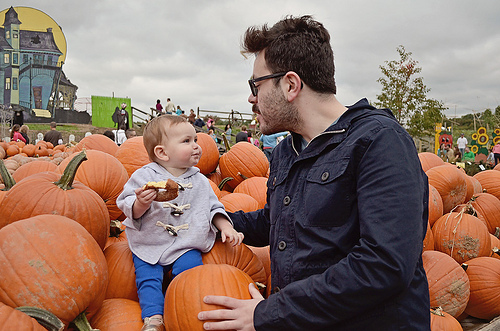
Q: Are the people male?
A: No, they are both male and female.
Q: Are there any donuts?
A: Yes, there is a donut.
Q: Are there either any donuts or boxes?
A: Yes, there is a donut.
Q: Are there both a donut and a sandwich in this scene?
A: No, there is a donut but no sandwiches.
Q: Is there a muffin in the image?
A: No, there are no muffins.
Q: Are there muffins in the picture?
A: No, there are no muffins.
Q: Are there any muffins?
A: No, there are no muffins.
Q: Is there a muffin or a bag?
A: No, there are no muffins or bags.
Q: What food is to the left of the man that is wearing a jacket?
A: The food is a donut.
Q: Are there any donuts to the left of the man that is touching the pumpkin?
A: Yes, there is a donut to the left of the man.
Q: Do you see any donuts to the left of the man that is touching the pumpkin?
A: Yes, there is a donut to the left of the man.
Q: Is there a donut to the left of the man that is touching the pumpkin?
A: Yes, there is a donut to the left of the man.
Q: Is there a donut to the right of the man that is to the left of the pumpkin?
A: No, the donut is to the left of the man.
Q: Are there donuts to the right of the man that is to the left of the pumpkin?
A: No, the donut is to the left of the man.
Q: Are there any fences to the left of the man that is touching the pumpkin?
A: No, there is a donut to the left of the man.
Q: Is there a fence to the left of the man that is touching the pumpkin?
A: No, there is a donut to the left of the man.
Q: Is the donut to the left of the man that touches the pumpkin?
A: Yes, the donut is to the left of the man.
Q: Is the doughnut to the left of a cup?
A: No, the doughnut is to the left of the man.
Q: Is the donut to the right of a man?
A: No, the donut is to the left of a man.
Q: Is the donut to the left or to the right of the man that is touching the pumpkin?
A: The donut is to the left of the man.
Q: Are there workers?
A: No, there are no workers.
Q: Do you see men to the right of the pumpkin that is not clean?
A: Yes, there is a man to the right of the pumpkin.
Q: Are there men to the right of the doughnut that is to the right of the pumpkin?
A: Yes, there is a man to the right of the doughnut.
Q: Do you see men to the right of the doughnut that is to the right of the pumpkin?
A: Yes, there is a man to the right of the doughnut.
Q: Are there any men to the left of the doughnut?
A: No, the man is to the right of the doughnut.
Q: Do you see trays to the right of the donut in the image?
A: No, there is a man to the right of the donut.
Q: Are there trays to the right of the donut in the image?
A: No, there is a man to the right of the donut.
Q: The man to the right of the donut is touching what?
A: The man is touching the pumpkin.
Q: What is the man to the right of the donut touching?
A: The man is touching the pumpkin.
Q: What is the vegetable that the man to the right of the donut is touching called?
A: The vegetable is a pumpkin.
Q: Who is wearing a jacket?
A: The man is wearing a jacket.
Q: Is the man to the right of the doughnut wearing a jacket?
A: Yes, the man is wearing a jacket.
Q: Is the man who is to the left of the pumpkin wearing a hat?
A: No, the man is wearing a jacket.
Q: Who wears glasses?
A: The man wears glasses.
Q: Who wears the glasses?
A: The man wears glasses.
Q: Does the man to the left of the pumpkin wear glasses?
A: Yes, the man wears glasses.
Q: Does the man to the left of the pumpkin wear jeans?
A: No, the man wears glasses.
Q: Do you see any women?
A: Yes, there is a woman.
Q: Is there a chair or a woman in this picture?
A: Yes, there is a woman.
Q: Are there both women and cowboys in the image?
A: No, there is a woman but no cowboys.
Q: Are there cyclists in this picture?
A: No, there are no cyclists.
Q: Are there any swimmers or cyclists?
A: No, there are no cyclists or swimmers.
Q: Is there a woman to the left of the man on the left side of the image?
A: Yes, there is a woman to the left of the man.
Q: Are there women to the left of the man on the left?
A: Yes, there is a woman to the left of the man.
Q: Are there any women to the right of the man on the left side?
A: No, the woman is to the left of the man.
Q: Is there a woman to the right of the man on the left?
A: No, the woman is to the left of the man.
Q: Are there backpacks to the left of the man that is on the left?
A: No, there is a woman to the left of the man.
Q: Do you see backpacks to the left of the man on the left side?
A: No, there is a woman to the left of the man.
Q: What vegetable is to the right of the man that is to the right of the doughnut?
A: The vegetable is a pumpkin.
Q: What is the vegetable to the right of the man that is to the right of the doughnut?
A: The vegetable is a pumpkin.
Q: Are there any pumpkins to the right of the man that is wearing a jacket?
A: Yes, there is a pumpkin to the right of the man.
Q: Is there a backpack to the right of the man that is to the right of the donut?
A: No, there is a pumpkin to the right of the man.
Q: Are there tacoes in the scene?
A: No, there are no tacoes.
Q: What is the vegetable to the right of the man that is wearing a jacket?
A: The vegetable is a pumpkin.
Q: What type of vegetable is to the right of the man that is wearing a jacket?
A: The vegetable is a pumpkin.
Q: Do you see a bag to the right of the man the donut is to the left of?
A: No, there is a pumpkin to the right of the man.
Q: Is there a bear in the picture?
A: No, there are no bears.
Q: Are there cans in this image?
A: No, there are no cans.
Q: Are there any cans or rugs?
A: No, there are no cans or rugs.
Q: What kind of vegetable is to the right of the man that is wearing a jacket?
A: The vegetable is a pumpkin.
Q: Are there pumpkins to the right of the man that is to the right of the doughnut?
A: Yes, there is a pumpkin to the right of the man.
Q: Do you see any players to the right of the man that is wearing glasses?
A: No, there is a pumpkin to the right of the man.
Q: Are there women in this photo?
A: Yes, there is a woman.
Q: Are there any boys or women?
A: Yes, there is a woman.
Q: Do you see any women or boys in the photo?
A: Yes, there is a woman.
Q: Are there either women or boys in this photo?
A: Yes, there is a woman.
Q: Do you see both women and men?
A: Yes, there are both a woman and a man.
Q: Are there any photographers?
A: No, there are no photographers.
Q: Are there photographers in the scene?
A: No, there are no photographers.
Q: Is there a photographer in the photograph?
A: No, there are no photographers.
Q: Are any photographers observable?
A: No, there are no photographers.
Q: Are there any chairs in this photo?
A: No, there are no chairs.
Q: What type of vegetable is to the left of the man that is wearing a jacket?
A: The vegetable is a pumpkin.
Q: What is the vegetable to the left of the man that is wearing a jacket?
A: The vegetable is a pumpkin.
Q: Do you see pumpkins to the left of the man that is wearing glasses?
A: Yes, there is a pumpkin to the left of the man.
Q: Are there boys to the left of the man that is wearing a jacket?
A: No, there is a pumpkin to the left of the man.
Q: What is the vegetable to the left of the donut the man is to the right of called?
A: The vegetable is a pumpkin.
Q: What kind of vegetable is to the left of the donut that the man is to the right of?
A: The vegetable is a pumpkin.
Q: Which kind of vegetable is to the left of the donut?
A: The vegetable is a pumpkin.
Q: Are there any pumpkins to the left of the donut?
A: Yes, there is a pumpkin to the left of the donut.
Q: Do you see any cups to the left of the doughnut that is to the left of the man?
A: No, there is a pumpkin to the left of the doughnut.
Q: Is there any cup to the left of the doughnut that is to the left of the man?
A: No, there is a pumpkin to the left of the doughnut.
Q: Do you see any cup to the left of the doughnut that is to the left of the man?
A: No, there is a pumpkin to the left of the doughnut.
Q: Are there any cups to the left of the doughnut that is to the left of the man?
A: No, there is a pumpkin to the left of the doughnut.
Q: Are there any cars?
A: No, there are no cars.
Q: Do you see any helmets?
A: No, there are no helmets.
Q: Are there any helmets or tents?
A: No, there are no helmets or tents.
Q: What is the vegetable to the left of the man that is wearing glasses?
A: The vegetable is a pumpkin.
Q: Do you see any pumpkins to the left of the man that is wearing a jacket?
A: Yes, there is a pumpkin to the left of the man.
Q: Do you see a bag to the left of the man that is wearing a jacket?
A: No, there is a pumpkin to the left of the man.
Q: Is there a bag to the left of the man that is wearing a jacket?
A: No, there is a pumpkin to the left of the man.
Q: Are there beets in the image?
A: No, there are no beets.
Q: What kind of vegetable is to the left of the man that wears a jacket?
A: The vegetable is a pumpkin.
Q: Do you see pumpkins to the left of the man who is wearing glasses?
A: Yes, there is a pumpkin to the left of the man.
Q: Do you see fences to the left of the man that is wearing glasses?
A: No, there is a pumpkin to the left of the man.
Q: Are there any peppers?
A: No, there are no peppers.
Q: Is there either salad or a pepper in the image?
A: No, there are no peppers or salad.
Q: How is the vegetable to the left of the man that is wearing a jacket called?
A: The vegetable is a pumpkin.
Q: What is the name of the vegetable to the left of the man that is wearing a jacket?
A: The vegetable is a pumpkin.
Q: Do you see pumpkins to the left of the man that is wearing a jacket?
A: Yes, there is a pumpkin to the left of the man.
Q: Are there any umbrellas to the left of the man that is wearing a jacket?
A: No, there is a pumpkin to the left of the man.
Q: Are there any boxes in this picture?
A: No, there are no boxes.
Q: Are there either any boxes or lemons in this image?
A: No, there are no boxes or lemons.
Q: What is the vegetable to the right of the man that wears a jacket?
A: The vegetable is a pumpkin.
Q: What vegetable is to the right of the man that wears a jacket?
A: The vegetable is a pumpkin.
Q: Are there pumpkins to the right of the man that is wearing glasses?
A: Yes, there is a pumpkin to the right of the man.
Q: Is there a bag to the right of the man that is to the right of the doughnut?
A: No, there is a pumpkin to the right of the man.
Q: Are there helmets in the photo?
A: No, there are no helmets.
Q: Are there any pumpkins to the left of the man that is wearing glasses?
A: Yes, there is a pumpkin to the left of the man.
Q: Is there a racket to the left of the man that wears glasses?
A: No, there is a pumpkin to the left of the man.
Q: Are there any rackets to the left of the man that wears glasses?
A: No, there is a pumpkin to the left of the man.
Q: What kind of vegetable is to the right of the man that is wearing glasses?
A: The vegetable is a pumpkin.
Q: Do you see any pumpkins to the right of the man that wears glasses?
A: Yes, there is a pumpkin to the right of the man.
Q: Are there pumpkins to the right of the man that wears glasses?
A: Yes, there is a pumpkin to the right of the man.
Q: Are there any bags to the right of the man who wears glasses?
A: No, there is a pumpkin to the right of the man.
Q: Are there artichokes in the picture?
A: No, there are no artichokes.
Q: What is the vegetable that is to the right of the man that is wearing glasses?
A: The vegetable is a pumpkin.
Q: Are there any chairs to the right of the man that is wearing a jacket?
A: No, there is a pumpkin to the right of the man.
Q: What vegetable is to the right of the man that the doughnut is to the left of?
A: The vegetable is a pumpkin.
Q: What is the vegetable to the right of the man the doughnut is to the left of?
A: The vegetable is a pumpkin.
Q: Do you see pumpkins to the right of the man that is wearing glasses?
A: Yes, there is a pumpkin to the right of the man.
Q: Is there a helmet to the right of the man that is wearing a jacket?
A: No, there is a pumpkin to the right of the man.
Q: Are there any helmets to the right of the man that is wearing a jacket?
A: No, there is a pumpkin to the right of the man.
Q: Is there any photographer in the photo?
A: No, there are no photographers.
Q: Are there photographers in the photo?
A: No, there are no photographers.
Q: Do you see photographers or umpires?
A: No, there are no photographers or umpires.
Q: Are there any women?
A: Yes, there is a woman.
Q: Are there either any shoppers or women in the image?
A: Yes, there is a woman.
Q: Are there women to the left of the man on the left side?
A: Yes, there is a woman to the left of the man.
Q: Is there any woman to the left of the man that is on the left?
A: Yes, there is a woman to the left of the man.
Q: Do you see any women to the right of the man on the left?
A: No, the woman is to the left of the man.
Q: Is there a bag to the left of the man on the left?
A: No, there is a woman to the left of the man.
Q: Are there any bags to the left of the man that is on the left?
A: No, there is a woman to the left of the man.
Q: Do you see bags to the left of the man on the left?
A: No, there is a woman to the left of the man.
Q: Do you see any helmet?
A: No, there are no helmets.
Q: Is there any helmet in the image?
A: No, there are no helmets.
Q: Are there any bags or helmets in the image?
A: No, there are no helmets or bags.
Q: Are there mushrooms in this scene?
A: No, there are no mushrooms.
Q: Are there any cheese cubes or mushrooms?
A: No, there are no mushrooms or cheese cubes.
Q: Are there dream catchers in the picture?
A: No, there are no dream catchers.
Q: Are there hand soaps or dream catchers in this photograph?
A: No, there are no dream catchers or hand soaps.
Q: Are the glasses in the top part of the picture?
A: Yes, the glasses are in the top of the image.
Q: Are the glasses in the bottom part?
A: No, the glasses are in the top of the image.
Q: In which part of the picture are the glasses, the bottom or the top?
A: The glasses are in the top of the image.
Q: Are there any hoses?
A: No, there are no hoses.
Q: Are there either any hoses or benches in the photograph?
A: No, there are no hoses or benches.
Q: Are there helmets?
A: No, there are no helmets.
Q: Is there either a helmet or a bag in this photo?
A: No, there are no helmets or bags.